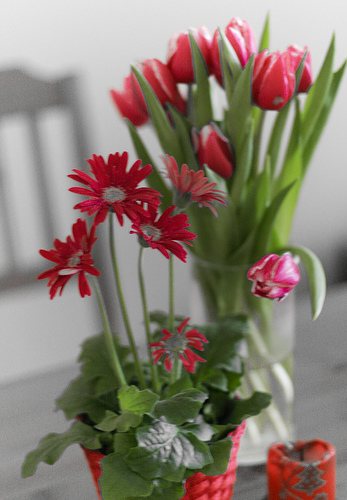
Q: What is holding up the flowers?
A: Stems.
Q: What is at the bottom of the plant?
A: Green leaves.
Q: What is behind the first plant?
A: A vase of tulips.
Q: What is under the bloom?
A: A stem.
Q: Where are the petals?
A: On flower.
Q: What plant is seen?
A: Flowers.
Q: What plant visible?
A: Flower.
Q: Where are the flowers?
A: In vase.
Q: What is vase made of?
A: Glass.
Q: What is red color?
A: Basket.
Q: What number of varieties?
A: Two.